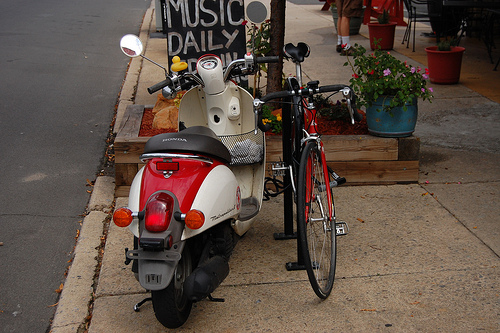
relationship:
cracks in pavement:
[415, 182, 497, 269] [49, 1, 499, 332]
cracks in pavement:
[97, 249, 492, 302] [49, 1, 499, 332]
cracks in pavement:
[413, 85, 485, 108] [49, 1, 499, 332]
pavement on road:
[18, 170, 95, 230] [8, 4, 150, 328]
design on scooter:
[231, 183, 245, 216] [103, 23, 285, 330]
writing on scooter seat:
[153, 133, 195, 142] [141, 116, 238, 168]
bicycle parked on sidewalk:
[265, 41, 350, 286] [349, 185, 499, 317]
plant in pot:
[340, 50, 431, 105] [366, 98, 414, 133]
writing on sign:
[162, 3, 244, 53] [147, 2, 253, 92]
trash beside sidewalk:
[71, 130, 132, 195] [122, 11, 494, 331]